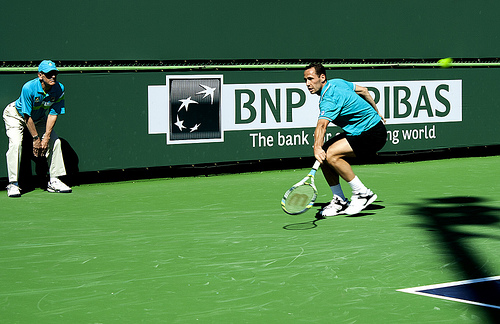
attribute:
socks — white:
[323, 175, 371, 195]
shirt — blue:
[311, 76, 383, 136]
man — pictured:
[304, 61, 386, 218]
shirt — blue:
[316, 76, 381, 135]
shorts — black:
[323, 121, 386, 157]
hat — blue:
[30, 56, 57, 79]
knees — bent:
[320, 144, 344, 164]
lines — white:
[395, 283, 422, 296]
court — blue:
[469, 282, 498, 301]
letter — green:
[432, 82, 455, 120]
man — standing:
[3, 50, 81, 200]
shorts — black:
[336, 112, 419, 158]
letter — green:
[232, 87, 259, 132]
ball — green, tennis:
[429, 41, 459, 66]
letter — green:
[412, 81, 437, 118]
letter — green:
[260, 89, 280, 124]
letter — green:
[282, 82, 307, 124]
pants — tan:
[2, 100, 69, 181]